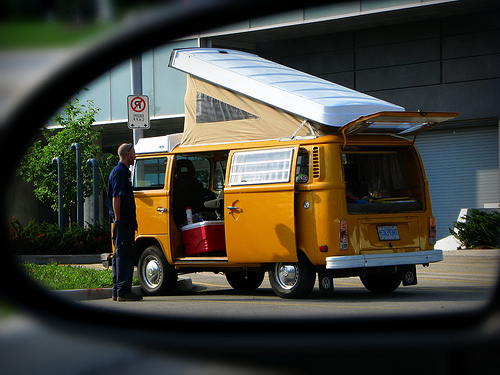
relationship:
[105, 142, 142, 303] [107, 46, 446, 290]
man by van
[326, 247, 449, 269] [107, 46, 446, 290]
bumper on van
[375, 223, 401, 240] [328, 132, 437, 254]
plate on back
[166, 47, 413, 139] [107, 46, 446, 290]
popup on van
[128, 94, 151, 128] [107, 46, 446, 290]
sign by van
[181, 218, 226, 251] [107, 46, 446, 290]
cooler in van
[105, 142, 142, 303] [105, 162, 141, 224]
man wears shirt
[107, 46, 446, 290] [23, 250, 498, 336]
van in lot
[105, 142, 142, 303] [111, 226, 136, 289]
man wears jeans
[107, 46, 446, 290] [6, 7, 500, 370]
van in mirror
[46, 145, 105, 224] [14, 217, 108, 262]
pipes by plantings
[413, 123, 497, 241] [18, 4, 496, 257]
gate on building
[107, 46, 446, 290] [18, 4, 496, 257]
van by building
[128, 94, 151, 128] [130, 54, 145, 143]
sign on pole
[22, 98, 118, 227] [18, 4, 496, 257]
tree by building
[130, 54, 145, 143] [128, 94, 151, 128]
pole by sign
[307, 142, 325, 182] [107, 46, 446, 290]
vents on van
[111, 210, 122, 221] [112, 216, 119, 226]
hand in pocket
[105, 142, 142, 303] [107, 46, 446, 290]
man looks at van